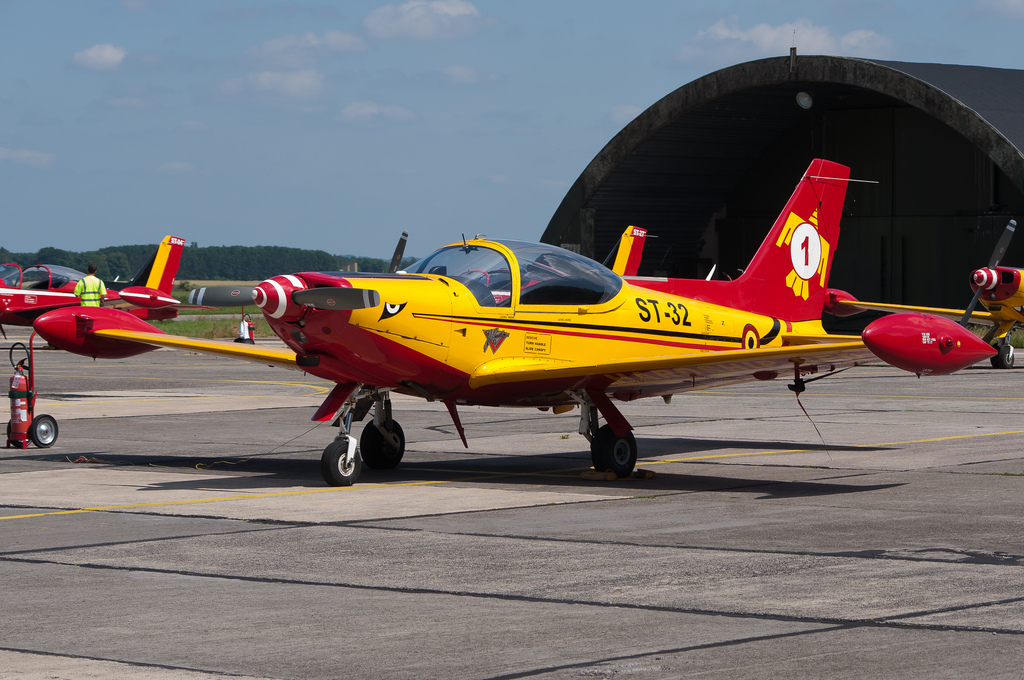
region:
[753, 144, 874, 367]
the tail of the plane is red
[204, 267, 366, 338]
the nose of the plane is red and white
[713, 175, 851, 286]
the number is red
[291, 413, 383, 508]
the wheel is black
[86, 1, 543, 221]
the sky is partly cloudy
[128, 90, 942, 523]
the plane is parked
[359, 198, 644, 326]
the plane is empty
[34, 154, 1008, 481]
Main red and yellow airplane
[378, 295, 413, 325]
Decal of plane that looks like an eye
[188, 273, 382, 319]
Propellor blades and nose cone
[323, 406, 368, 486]
Front wheel of landing gear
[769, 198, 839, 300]
Decal on tail depicting a bird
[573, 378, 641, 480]
Left rear wheel of landing gear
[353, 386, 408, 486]
Right rear wheel of landing gear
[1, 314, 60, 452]
Fire extinguisher on hand cart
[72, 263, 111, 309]
Man in bright safety shirt in background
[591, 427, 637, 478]
yellow plane has a tire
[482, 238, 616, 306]
plane has a window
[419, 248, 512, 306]
plane has a window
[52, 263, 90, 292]
plane has a window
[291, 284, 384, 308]
plane has a propeller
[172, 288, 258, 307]
plane has a propeller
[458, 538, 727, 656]
a view of road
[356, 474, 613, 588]
a view of floor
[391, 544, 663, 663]
a view of lines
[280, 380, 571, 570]
wheel of the plane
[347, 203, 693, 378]
glasses of the plane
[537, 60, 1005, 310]
a view of building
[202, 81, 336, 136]
a view of clouds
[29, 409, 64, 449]
round rubber black tire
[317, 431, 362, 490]
round rubber black tire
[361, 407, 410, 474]
round rubber black tire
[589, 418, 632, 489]
round rubber black tire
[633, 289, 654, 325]
black letter on plane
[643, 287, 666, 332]
black letter on plane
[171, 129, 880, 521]
Red and yellow plane on the runway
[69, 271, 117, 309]
man wearing a green safety jacket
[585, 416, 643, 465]
black wheel on the airplane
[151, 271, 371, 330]
propeller on the airplane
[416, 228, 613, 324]
window on the airplane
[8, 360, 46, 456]
fire extinguisher on the runway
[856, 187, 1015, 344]
airplane on the tarmac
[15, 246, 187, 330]
airplane on the tarmac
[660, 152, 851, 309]
airplane with a red tail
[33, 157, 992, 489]
a yellow and black airplane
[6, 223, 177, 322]
a yellow and black airplane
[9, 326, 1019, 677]
an airport tarmac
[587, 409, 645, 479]
an airplane tire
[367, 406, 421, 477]
an airplane tire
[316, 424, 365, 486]
an airplane tire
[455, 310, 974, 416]
an airplane wing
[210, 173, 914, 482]
red and yellow plane on the tarmac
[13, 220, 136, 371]
red and yellow plane with a guy by it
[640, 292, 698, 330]
ST-32 on the side of the plane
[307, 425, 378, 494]
front wheel on the plane on the ground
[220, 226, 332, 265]
mountain off in the distance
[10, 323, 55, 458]
red oxygen tank on the ground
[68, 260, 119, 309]
Man standing beside a red plane.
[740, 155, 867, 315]
Red tail on a yellow plane.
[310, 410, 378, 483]
Front wheel on a yellow plane.